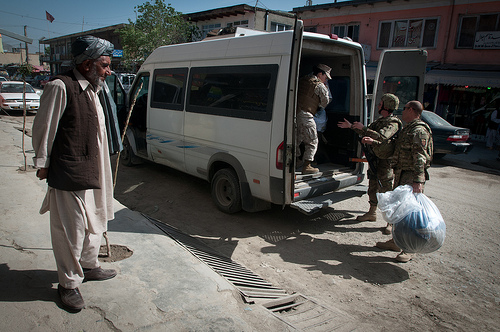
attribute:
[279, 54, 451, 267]
soldiers — american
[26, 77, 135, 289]
clothing — ethnic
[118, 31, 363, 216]
van — white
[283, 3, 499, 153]
building — old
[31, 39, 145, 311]
man — amused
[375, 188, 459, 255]
goods — plastic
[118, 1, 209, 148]
tree — green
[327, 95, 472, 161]
sedan — green, black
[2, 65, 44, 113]
sedan — white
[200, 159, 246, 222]
tire — black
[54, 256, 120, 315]
shoes — brown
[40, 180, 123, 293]
pants — beige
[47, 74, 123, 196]
vest — brown, dark brown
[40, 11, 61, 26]
flag — flying